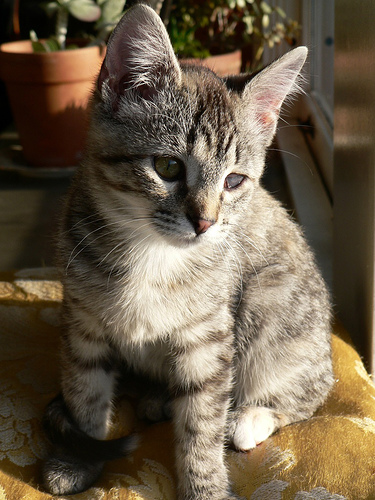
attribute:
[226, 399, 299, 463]
paw — white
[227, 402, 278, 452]
paw — white 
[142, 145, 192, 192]
eye — dark 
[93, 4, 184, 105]
ear — pink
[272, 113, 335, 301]
sill — window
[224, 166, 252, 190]
eye — milky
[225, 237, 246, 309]
whisker — long, white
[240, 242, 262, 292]
whisker — long, white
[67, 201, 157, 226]
whisker — long, white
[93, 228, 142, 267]
whisker — long, white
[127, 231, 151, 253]
whisker — long, white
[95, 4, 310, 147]
ears — big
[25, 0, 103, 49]
plant — potted